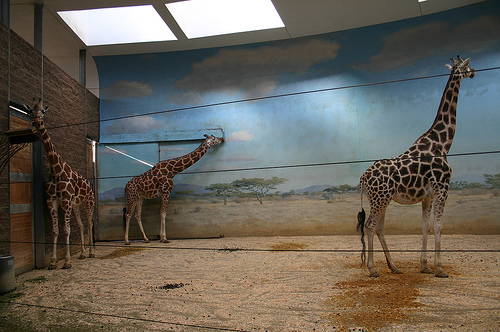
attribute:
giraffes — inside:
[17, 53, 478, 283]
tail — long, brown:
[350, 172, 370, 237]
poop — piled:
[157, 275, 189, 295]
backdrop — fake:
[97, 39, 498, 239]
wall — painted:
[95, 30, 498, 235]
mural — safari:
[95, 48, 498, 238]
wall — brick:
[17, 52, 87, 139]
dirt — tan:
[133, 246, 331, 329]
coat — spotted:
[130, 174, 170, 203]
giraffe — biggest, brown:
[346, 46, 482, 287]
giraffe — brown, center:
[96, 104, 266, 248]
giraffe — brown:
[15, 100, 105, 263]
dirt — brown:
[144, 240, 333, 330]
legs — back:
[349, 167, 400, 272]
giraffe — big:
[328, 47, 491, 262]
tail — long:
[334, 172, 384, 250]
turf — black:
[344, 172, 384, 251]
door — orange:
[6, 112, 49, 277]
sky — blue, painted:
[107, 39, 447, 199]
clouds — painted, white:
[192, 47, 332, 89]